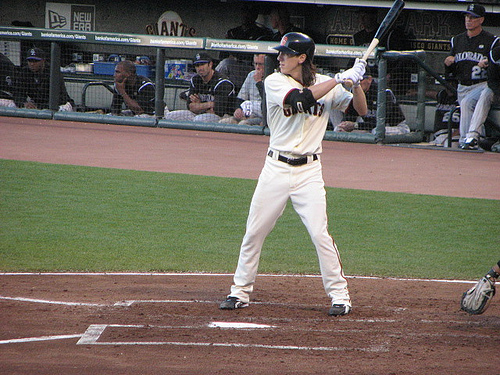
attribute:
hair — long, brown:
[303, 63, 319, 92]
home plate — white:
[207, 307, 273, 339]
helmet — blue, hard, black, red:
[270, 31, 329, 62]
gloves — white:
[336, 66, 371, 83]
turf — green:
[73, 194, 226, 272]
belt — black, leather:
[266, 149, 329, 163]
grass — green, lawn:
[18, 174, 469, 268]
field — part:
[1, 145, 492, 369]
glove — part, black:
[457, 269, 500, 325]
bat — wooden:
[372, 4, 403, 71]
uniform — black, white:
[268, 98, 327, 254]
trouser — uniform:
[265, 157, 336, 262]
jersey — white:
[257, 87, 333, 147]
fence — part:
[45, 50, 275, 124]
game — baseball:
[10, 65, 405, 374]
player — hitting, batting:
[266, 9, 368, 253]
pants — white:
[251, 150, 343, 307]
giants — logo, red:
[135, 15, 225, 51]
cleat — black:
[316, 303, 351, 319]